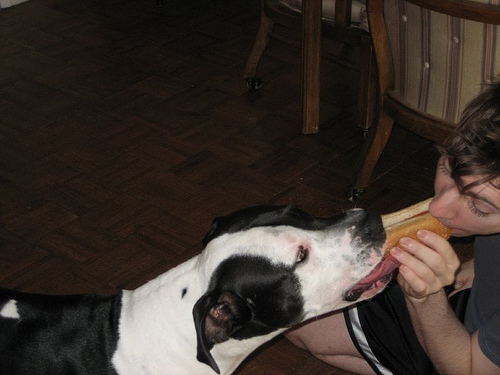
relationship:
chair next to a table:
[244, 2, 361, 137] [340, 2, 484, 8]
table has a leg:
[340, 2, 484, 8] [301, 1, 319, 135]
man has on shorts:
[280, 81, 500, 374] [343, 281, 472, 373]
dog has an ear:
[2, 202, 393, 373] [192, 291, 245, 374]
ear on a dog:
[192, 291, 245, 374] [2, 202, 393, 373]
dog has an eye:
[2, 202, 393, 373] [297, 248, 308, 265]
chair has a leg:
[244, 2, 361, 137] [301, 1, 319, 135]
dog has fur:
[2, 202, 393, 373] [113, 305, 177, 353]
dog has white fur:
[2, 202, 393, 373] [147, 301, 174, 338]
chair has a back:
[244, 2, 361, 137] [382, 2, 499, 124]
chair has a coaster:
[244, 2, 361, 137] [248, 79, 263, 91]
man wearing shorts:
[280, 81, 500, 374] [343, 281, 472, 373]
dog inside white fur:
[2, 202, 393, 373] [147, 301, 174, 338]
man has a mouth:
[280, 81, 500, 374] [433, 214, 474, 239]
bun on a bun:
[377, 197, 459, 261] [381, 212, 450, 252]